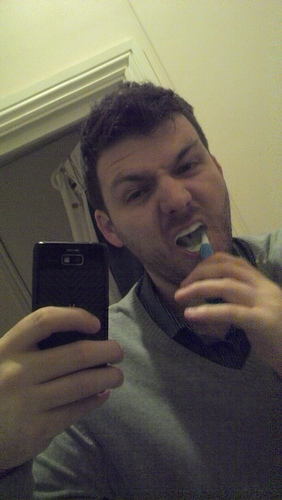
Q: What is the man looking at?
A: Phone.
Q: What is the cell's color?
A: Black.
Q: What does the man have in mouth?
A: Toothbrush.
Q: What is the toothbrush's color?
A: Blue and white.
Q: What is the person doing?
A: Taking a selfie.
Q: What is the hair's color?
A: Brown.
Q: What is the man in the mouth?
A: Toothbrush.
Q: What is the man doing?
A: Using a toothbrush.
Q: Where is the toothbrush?
A: In the man's left hand.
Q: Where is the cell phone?
A: In the man's right hand.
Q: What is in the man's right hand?
A: A cell phone.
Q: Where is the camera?
A: On the phone.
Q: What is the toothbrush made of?
A: Plastic.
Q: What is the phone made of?
A: Metal.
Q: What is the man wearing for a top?
A: A gray sweater.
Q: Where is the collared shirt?
A: Under the sweater.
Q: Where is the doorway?
A: Behind the man.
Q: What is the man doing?
A: Taking a selfie.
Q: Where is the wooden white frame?
A: Over the door.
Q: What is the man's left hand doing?
A: Brushing his teeth.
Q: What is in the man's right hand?
A: A cell phone.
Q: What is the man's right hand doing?
A: Taking a picture.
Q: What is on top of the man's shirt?
A: A gray sweater.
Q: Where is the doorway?
A: Behind the man.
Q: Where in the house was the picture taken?
A: Bathroom.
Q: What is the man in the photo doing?
A: Brushing his teeth.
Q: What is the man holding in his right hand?
A: A smartphone.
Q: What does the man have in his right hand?
A: A toothbrush.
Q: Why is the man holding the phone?
A: To take a picture in the mirror.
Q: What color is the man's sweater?
A: Gray.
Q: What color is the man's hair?
A: Brown.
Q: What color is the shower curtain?
A: White.